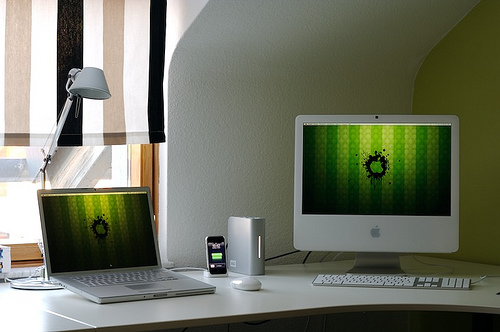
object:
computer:
[294, 113, 472, 290]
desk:
[0, 252, 498, 332]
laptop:
[36, 185, 218, 305]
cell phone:
[203, 234, 230, 277]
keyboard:
[310, 273, 473, 291]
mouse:
[229, 275, 263, 291]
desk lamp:
[8, 65, 112, 292]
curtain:
[1, 0, 167, 144]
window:
[0, 0, 164, 268]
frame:
[1, 143, 161, 267]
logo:
[369, 224, 382, 238]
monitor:
[291, 112, 462, 255]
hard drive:
[225, 216, 267, 276]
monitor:
[36, 185, 162, 274]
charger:
[202, 269, 231, 278]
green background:
[303, 124, 450, 216]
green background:
[38, 191, 159, 272]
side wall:
[411, 1, 500, 266]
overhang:
[167, 0, 479, 87]